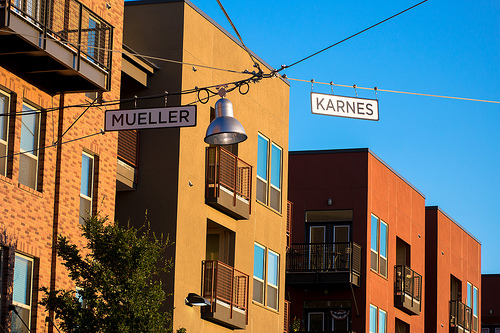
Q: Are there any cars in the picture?
A: No, there are no cars.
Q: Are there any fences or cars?
A: No, there are no cars or fences.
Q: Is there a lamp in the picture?
A: Yes, there is a lamp.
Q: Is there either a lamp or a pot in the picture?
A: Yes, there is a lamp.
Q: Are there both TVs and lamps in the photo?
A: No, there is a lamp but no televisions.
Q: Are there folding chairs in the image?
A: No, there are no folding chairs.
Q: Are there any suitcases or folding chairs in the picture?
A: No, there are no folding chairs or suitcases.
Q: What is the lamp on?
A: The lamp is on the wire.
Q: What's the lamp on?
A: The lamp is on the wire.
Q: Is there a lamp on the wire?
A: Yes, there is a lamp on the wire.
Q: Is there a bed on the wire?
A: No, there is a lamp on the wire.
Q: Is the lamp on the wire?
A: Yes, the lamp is on the wire.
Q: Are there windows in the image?
A: Yes, there is a window.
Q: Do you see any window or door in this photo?
A: Yes, there is a window.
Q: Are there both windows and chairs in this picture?
A: No, there is a window but no chairs.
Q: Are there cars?
A: No, there are no cars.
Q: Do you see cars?
A: No, there are no cars.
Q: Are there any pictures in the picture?
A: No, there are no pictures.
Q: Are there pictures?
A: No, there are no pictures.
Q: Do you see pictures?
A: No, there are no pictures.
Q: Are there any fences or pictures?
A: No, there are no pictures or fences.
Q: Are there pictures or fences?
A: No, there are no pictures or fences.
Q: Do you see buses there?
A: No, there are no buses.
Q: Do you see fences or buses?
A: No, there are no buses or fences.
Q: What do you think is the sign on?
A: The sign is on the wire.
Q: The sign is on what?
A: The sign is on the wire.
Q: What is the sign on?
A: The sign is on the wire.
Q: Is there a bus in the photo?
A: No, there are no buses.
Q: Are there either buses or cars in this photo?
A: No, there are no buses or cars.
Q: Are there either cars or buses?
A: No, there are no buses or cars.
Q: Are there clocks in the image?
A: No, there are no clocks.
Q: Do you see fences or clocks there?
A: No, there are no clocks or fences.